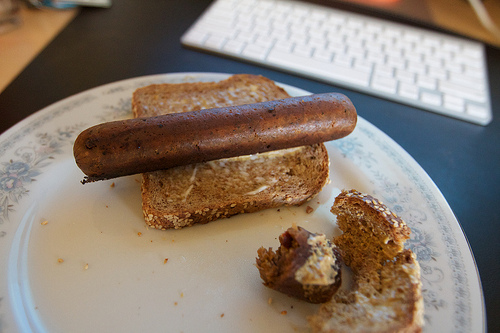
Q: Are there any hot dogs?
A: Yes, there is a hot dog.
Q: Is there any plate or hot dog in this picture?
A: Yes, there is a hot dog.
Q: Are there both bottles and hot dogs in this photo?
A: No, there is a hot dog but no bottles.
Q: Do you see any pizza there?
A: No, there are no pizzas.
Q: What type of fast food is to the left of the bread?
A: The food is a hot dog.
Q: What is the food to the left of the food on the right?
A: The food is a hot dog.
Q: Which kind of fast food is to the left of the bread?
A: The food is a hot dog.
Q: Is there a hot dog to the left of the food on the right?
A: Yes, there is a hot dog to the left of the bread.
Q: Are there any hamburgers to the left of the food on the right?
A: No, there is a hot dog to the left of the bread.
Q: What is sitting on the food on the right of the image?
A: The hot dog is sitting on the bread.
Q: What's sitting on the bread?
A: The hot dog is sitting on the bread.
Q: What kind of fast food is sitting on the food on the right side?
A: The food is a hot dog.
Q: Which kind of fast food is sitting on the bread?
A: The food is a hot dog.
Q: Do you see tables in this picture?
A: Yes, there is a table.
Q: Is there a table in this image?
A: Yes, there is a table.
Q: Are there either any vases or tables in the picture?
A: Yes, there is a table.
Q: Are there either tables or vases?
A: Yes, there is a table.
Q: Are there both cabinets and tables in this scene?
A: No, there is a table but no cabinets.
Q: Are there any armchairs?
A: No, there are no armchairs.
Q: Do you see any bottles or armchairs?
A: No, there are no armchairs or bottles.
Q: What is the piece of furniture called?
A: The piece of furniture is a table.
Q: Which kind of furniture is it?
A: The piece of furniture is a table.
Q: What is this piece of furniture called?
A: This is a table.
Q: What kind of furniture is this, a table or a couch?
A: This is a table.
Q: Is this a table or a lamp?
A: This is a table.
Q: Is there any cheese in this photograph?
A: No, there is no cheese.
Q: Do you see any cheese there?
A: No, there is no cheese.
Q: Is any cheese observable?
A: No, there is no cheese.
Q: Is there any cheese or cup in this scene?
A: No, there are no cheese or cups.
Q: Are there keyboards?
A: Yes, there is a keyboard.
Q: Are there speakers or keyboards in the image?
A: Yes, there is a keyboard.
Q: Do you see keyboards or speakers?
A: Yes, there is a keyboard.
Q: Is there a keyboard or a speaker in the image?
A: Yes, there is a keyboard.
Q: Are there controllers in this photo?
A: No, there are no controllers.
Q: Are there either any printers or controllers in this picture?
A: No, there are no controllers or printers.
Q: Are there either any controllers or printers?
A: No, there are no controllers or printers.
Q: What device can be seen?
A: The device is a keyboard.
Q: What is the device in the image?
A: The device is a keyboard.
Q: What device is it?
A: The device is a keyboard.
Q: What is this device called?
A: This is a keyboard.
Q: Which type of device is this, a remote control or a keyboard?
A: This is a keyboard.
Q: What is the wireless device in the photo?
A: The device is a keyboard.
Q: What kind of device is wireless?
A: The device is a keyboard.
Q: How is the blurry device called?
A: The device is a keyboard.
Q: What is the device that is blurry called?
A: The device is a keyboard.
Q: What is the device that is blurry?
A: The device is a keyboard.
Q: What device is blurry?
A: The device is a keyboard.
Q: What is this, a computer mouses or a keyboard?
A: This is a keyboard.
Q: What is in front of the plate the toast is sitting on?
A: The keyboard is in front of the plate.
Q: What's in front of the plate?
A: The keyboard is in front of the plate.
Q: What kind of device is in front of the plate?
A: The device is a keyboard.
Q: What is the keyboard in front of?
A: The keyboard is in front of the plate.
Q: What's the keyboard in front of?
A: The keyboard is in front of the plate.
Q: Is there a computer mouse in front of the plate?
A: No, there is a keyboard in front of the plate.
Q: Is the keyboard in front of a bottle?
A: No, the keyboard is in front of the plate.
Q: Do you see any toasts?
A: Yes, there is a toast.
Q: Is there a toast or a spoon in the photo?
A: Yes, there is a toast.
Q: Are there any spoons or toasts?
A: Yes, there is a toast.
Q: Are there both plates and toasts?
A: Yes, there are both a toast and a plate.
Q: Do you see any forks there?
A: No, there are no forks.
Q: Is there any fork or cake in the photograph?
A: No, there are no forks or cakes.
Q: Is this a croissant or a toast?
A: This is a toast.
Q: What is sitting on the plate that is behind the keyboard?
A: The toast is sitting on the plate.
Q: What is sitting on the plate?
A: The toast is sitting on the plate.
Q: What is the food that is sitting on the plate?
A: The food is a toast.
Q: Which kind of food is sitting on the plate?
A: The food is a toast.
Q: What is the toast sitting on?
A: The toast is sitting on the plate.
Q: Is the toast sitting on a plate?
A: Yes, the toast is sitting on a plate.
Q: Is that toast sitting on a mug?
A: No, the toast is sitting on a plate.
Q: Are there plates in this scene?
A: Yes, there is a plate.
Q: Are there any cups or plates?
A: Yes, there is a plate.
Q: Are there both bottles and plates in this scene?
A: No, there is a plate but no bottles.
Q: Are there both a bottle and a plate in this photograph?
A: No, there is a plate but no bottles.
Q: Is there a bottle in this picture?
A: No, there are no bottles.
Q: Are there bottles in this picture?
A: No, there are no bottles.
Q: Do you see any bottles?
A: No, there are no bottles.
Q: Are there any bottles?
A: No, there are no bottles.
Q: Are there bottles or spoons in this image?
A: No, there are no bottles or spoons.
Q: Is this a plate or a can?
A: This is a plate.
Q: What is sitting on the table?
A: The plate is sitting on the table.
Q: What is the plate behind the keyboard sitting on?
A: The plate is sitting on the table.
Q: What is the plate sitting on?
A: The plate is sitting on the table.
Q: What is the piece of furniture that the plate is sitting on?
A: The piece of furniture is a table.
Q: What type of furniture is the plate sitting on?
A: The plate is sitting on the table.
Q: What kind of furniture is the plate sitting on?
A: The plate is sitting on the table.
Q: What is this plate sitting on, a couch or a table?
A: The plate is sitting on a table.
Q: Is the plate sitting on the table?
A: Yes, the plate is sitting on the table.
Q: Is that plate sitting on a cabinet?
A: No, the plate is sitting on the table.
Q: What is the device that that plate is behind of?
A: The device is a keyboard.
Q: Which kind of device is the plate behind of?
A: The plate is behind the keyboard.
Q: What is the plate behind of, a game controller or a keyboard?
A: The plate is behind a keyboard.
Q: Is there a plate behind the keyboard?
A: Yes, there is a plate behind the keyboard.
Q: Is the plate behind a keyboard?
A: Yes, the plate is behind a keyboard.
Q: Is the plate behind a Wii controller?
A: No, the plate is behind a keyboard.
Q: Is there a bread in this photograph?
A: Yes, there is a bread.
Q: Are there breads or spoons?
A: Yes, there is a bread.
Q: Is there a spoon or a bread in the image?
A: Yes, there is a bread.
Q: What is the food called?
A: The food is a bread.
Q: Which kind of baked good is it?
A: The food is a bread.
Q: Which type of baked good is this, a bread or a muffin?
A: That is a bread.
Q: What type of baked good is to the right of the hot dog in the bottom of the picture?
A: The food is a bread.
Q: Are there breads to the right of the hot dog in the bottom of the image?
A: Yes, there is a bread to the right of the hot dog.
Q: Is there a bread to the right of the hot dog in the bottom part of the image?
A: Yes, there is a bread to the right of the hot dog.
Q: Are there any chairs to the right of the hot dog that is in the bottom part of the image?
A: No, there is a bread to the right of the hot dog.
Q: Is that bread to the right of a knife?
A: No, the bread is to the right of the hot dog.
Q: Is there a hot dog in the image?
A: Yes, there is a hot dog.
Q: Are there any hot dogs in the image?
A: Yes, there is a hot dog.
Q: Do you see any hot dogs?
A: Yes, there is a hot dog.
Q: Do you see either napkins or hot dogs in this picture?
A: Yes, there is a hot dog.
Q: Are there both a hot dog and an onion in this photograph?
A: No, there is a hot dog but no onions.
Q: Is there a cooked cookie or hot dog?
A: Yes, there is a cooked hot dog.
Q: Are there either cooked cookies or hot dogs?
A: Yes, there is a cooked hot dog.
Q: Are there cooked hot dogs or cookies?
A: Yes, there is a cooked hot dog.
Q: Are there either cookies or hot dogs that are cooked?
A: Yes, the hot dog is cooked.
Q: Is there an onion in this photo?
A: No, there are no onions.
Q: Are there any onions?
A: No, there are no onions.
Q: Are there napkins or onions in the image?
A: No, there are no onions or napkins.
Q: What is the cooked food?
A: The food is a hot dog.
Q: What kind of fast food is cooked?
A: The fast food is a hot dog.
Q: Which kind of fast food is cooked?
A: The fast food is a hot dog.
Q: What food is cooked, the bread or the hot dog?
A: The hot dog is cooked.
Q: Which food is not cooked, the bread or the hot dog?
A: The bread is not cooked.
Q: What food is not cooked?
A: The food is a bread.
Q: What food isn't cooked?
A: The food is a bread.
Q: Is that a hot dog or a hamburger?
A: That is a hot dog.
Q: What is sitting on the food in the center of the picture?
A: The hot dog is sitting on the toast.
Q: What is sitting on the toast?
A: The hot dog is sitting on the toast.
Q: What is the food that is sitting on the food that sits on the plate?
A: The food is a hot dog.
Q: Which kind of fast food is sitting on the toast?
A: The food is a hot dog.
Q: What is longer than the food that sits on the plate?
A: The hot dog is longer than the toast.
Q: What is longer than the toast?
A: The hot dog is longer than the toast.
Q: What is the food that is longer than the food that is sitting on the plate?
A: The food is a hot dog.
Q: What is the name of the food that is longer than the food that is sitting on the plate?
A: The food is a hot dog.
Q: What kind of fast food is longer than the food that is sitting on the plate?
A: The food is a hot dog.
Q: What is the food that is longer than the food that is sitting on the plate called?
A: The food is a hot dog.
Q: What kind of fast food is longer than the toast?
A: The food is a hot dog.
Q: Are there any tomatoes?
A: No, there are no tomatoes.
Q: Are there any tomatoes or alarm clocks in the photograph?
A: No, there are no tomatoes or alarm clocks.